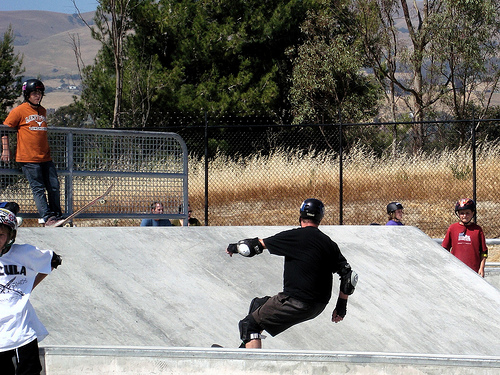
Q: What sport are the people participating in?
A: Skateboarding.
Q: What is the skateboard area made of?
A: Concrete.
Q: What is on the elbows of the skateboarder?
A: Elbow pads.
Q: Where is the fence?
A: Around the skateboard area.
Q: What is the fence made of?
A: Metal.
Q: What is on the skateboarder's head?
A: Helmet.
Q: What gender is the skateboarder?
A: Male.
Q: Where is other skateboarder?
A: On ramp.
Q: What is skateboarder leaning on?
A: Railing.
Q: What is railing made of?
A: Metal.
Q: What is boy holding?
A: Skateboard.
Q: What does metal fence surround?
A: Area.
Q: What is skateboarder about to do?
A: Trick.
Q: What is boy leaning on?
A: Fence.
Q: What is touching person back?
A: Hands.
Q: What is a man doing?
A: Skateboarding.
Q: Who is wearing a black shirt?
A: Man skateboarding.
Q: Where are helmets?
A: On the men's heads.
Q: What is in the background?
A: Trees.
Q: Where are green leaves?
A: On trees.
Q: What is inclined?
A: Skateboard ramp.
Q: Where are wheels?
A: On the skateboard.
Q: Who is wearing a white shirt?
A: Person on the left.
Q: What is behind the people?
A: A fence.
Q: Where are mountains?
A: In the distance.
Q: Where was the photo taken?
A: In a skate park.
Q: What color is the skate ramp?
A: Gray.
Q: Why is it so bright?
A: Sunny.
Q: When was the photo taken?
A: Day time.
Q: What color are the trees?
A: Green.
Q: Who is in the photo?
A: Boys.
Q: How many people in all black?
A: One.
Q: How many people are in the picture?
A: Seven.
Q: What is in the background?
A: Trees.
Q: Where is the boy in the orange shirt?
A: Top of ramp.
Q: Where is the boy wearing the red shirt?
A: Right.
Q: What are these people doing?
A: Skateboarding.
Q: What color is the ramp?
A: Gray.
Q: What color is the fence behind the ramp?
A: Black.